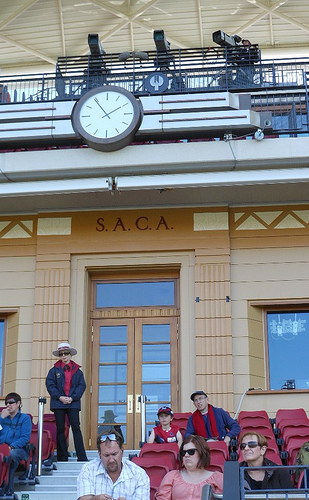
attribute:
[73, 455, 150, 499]
shirt — white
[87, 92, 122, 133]
face — white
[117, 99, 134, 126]
numbers — brown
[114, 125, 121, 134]
line — black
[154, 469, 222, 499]
shirt — pink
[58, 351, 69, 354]
sunglasses — dark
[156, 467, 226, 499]
shirt — pink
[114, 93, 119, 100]
line — black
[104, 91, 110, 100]
line — black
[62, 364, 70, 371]
tie — black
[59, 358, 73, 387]
shirt — red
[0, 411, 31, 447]
jacket — blue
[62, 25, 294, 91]
cameras — television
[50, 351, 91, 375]
scarf — red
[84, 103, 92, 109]
line — black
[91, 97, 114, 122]
line — black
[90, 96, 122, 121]
line — black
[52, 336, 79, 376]
hat — white